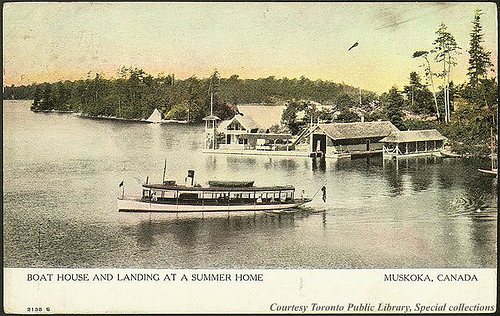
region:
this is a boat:
[121, 182, 311, 206]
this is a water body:
[359, 211, 439, 269]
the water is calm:
[328, 236, 373, 263]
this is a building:
[367, 130, 434, 157]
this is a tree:
[435, 15, 471, 92]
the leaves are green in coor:
[433, 30, 449, 52]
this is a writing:
[382, 264, 492, 301]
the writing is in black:
[386, 267, 486, 287]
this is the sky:
[182, 13, 266, 53]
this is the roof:
[331, 113, 355, 131]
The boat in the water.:
[116, 168, 308, 220]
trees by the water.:
[104, 54, 276, 106]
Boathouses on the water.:
[303, 120, 440, 161]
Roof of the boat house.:
[321, 119, 396, 135]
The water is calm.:
[33, 134, 134, 188]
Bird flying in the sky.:
[340, 32, 358, 50]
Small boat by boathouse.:
[439, 141, 470, 161]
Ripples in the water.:
[393, 178, 488, 222]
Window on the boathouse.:
[228, 122, 240, 133]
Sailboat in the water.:
[148, 104, 172, 131]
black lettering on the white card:
[14, 265, 496, 315]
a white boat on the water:
[100, 165, 346, 240]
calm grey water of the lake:
[23, 181, 98, 251]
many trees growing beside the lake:
[45, 54, 205, 118]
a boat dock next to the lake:
[375, 123, 446, 165]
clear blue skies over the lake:
[148, 15, 305, 61]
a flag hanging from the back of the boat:
[303, 179, 345, 207]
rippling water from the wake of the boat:
[329, 193, 483, 228]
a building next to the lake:
[196, 98, 361, 165]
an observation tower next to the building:
[199, 109, 226, 152]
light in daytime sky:
[7, 2, 494, 74]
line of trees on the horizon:
[6, 70, 374, 112]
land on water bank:
[27, 84, 202, 151]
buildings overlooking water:
[202, 109, 444, 177]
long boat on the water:
[5, 174, 442, 268]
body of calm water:
[3, 114, 486, 264]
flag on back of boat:
[116, 175, 332, 225]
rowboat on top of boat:
[116, 168, 313, 213]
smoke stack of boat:
[183, 167, 196, 194]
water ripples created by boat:
[283, 184, 490, 222]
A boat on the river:
[113, 165, 325, 218]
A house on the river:
[217, 100, 301, 155]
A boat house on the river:
[306, 113, 396, 170]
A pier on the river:
[376, 123, 449, 173]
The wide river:
[2, 99, 498, 266]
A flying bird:
[344, 34, 360, 54]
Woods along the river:
[3, 65, 375, 122]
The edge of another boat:
[474, 121, 499, 179]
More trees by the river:
[380, 24, 496, 155]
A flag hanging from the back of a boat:
[309, 180, 331, 206]